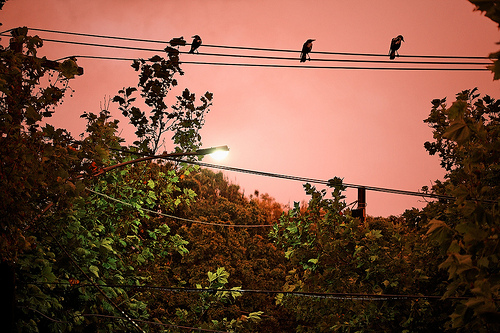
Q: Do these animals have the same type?
A: No, there are both birds and cows.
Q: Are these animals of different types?
A: Yes, they are birds and cows.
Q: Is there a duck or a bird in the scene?
A: Yes, there is a bird.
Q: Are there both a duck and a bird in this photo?
A: No, there is a bird but no ducks.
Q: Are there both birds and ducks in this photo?
A: No, there is a bird but no ducks.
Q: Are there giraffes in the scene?
A: No, there are no giraffes.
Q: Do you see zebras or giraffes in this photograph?
A: No, there are no giraffes or zebras.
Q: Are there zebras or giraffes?
A: No, there are no giraffes or zebras.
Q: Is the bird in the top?
A: Yes, the bird is in the top of the image.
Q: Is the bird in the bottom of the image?
A: No, the bird is in the top of the image.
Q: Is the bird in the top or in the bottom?
A: The bird is in the top of the image.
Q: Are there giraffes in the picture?
A: No, there are no giraffes.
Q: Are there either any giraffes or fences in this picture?
A: No, there are no giraffes or fences.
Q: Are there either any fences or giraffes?
A: No, there are no giraffes or fences.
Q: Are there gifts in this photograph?
A: No, there are no gifts.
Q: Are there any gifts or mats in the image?
A: No, there are no gifts or mats.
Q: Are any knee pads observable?
A: No, there are no knee pads.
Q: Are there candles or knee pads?
A: No, there are no knee pads or candles.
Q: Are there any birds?
A: Yes, there is a bird.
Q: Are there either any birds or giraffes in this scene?
A: Yes, there is a bird.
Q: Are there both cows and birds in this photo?
A: Yes, there are both a bird and cows.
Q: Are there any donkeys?
A: No, there are no donkeys.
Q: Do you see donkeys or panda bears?
A: No, there are no donkeys or panda bears.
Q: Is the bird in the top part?
A: Yes, the bird is in the top of the image.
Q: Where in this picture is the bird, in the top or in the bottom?
A: The bird is in the top of the image.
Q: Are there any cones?
A: No, there are no cones.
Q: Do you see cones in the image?
A: No, there are no cones.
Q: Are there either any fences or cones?
A: No, there are no cones or fences.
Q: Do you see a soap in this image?
A: No, there are no soaps.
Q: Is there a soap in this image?
A: No, there are no soaps.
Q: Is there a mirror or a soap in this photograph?
A: No, there are no soaps or mirrors.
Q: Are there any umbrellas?
A: No, there are no umbrellas.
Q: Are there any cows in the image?
A: Yes, there is a cow.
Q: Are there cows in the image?
A: Yes, there is a cow.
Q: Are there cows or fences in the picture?
A: Yes, there is a cow.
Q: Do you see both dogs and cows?
A: No, there is a cow but no dogs.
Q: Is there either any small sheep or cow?
A: Yes, there is a small cow.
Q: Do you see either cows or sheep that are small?
A: Yes, the cow is small.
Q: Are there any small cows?
A: Yes, there is a small cow.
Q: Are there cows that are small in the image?
A: Yes, there is a small cow.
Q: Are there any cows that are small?
A: Yes, there is a cow that is small.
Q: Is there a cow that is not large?
A: Yes, there is a small cow.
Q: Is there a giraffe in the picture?
A: No, there are no giraffes.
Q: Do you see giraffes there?
A: No, there are no giraffes.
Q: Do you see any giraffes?
A: No, there are no giraffes.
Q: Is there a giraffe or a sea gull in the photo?
A: No, there are no giraffes or seagulls.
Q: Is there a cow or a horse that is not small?
A: No, there is a cow but it is small.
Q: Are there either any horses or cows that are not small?
A: No, there is a cow but it is small.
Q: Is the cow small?
A: Yes, the cow is small.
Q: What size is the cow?
A: The cow is small.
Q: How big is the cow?
A: The cow is small.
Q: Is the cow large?
A: No, the cow is small.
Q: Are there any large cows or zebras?
A: No, there is a cow but it is small.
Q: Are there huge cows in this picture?
A: No, there is a cow but it is small.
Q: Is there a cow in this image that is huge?
A: No, there is a cow but it is small.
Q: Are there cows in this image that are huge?
A: No, there is a cow but it is small.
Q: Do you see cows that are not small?
A: No, there is a cow but it is small.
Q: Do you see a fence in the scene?
A: No, there are no fences.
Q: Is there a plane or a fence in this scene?
A: No, there are no fences or airplanes.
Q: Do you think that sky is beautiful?
A: Yes, the sky is beautiful.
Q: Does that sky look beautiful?
A: Yes, the sky is beautiful.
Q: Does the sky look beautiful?
A: Yes, the sky is beautiful.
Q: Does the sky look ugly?
A: No, the sky is beautiful.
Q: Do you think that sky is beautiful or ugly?
A: The sky is beautiful.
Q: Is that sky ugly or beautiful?
A: The sky is beautiful.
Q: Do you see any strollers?
A: No, there are no strollers.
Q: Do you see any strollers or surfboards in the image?
A: No, there are no strollers or surfboards.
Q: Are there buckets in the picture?
A: No, there are no buckets.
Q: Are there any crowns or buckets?
A: No, there are no buckets or crowns.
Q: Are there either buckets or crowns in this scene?
A: No, there are no buckets or crowns.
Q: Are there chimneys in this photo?
A: No, there are no chimneys.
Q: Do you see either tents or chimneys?
A: No, there are no chimneys or tents.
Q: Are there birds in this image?
A: Yes, there is a bird.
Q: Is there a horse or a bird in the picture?
A: Yes, there is a bird.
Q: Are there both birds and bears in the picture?
A: No, there is a bird but no bears.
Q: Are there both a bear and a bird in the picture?
A: No, there is a bird but no bears.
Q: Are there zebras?
A: No, there are no zebras.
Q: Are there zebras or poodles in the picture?
A: No, there are no zebras or poodles.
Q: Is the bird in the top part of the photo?
A: Yes, the bird is in the top of the image.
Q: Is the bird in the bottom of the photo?
A: No, the bird is in the top of the image.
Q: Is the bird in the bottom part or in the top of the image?
A: The bird is in the top of the image.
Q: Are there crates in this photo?
A: No, there are no crates.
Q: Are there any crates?
A: No, there are no crates.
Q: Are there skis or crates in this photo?
A: No, there are no crates or skis.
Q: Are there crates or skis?
A: No, there are no crates or skis.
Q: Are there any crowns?
A: No, there are no crowns.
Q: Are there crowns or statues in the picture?
A: No, there are no crowns or statues.